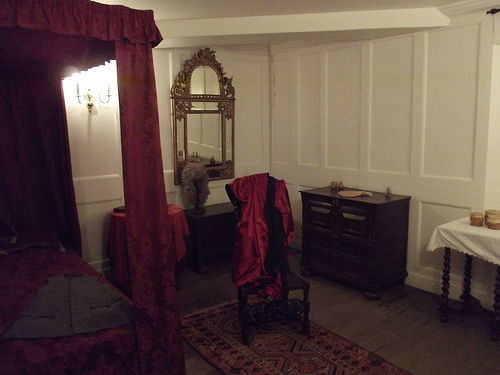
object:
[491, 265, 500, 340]
leg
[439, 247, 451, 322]
leg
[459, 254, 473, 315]
leg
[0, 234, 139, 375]
bed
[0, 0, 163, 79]
canopy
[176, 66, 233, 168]
mirror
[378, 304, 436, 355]
floor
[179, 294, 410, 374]
carpet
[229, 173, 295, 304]
clothing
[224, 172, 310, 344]
chair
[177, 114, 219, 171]
reflection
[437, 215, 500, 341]
table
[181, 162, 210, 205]
wig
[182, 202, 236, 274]
cabinet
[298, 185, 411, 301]
dresser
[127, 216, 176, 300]
cloth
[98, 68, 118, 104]
light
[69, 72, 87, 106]
light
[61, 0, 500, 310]
wall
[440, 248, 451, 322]
stick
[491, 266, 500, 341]
stick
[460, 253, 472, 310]
stick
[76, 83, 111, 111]
candlestick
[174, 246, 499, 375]
ground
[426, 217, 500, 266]
tablecloth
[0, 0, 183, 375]
bed dressings